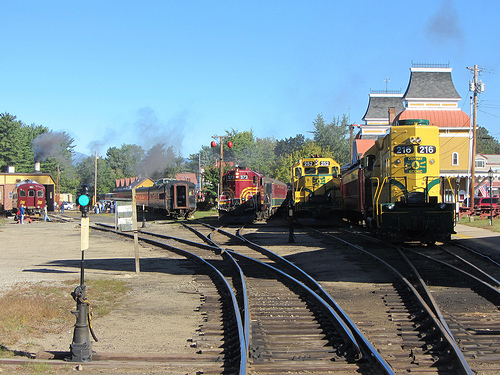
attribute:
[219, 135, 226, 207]
light — turuoise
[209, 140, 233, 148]
pole — large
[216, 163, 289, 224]
car — road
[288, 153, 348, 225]
train — yellow, green, colored, metal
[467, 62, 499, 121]
line — power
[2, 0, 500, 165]
skies — blue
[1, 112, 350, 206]
trees — green, tall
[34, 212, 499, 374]
tracks — steel, rows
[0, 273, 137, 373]
grass — green, dried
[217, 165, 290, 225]
train — red, brown, colored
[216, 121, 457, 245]
trains — three, row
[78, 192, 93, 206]
light — green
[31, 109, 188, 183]
smoke — air